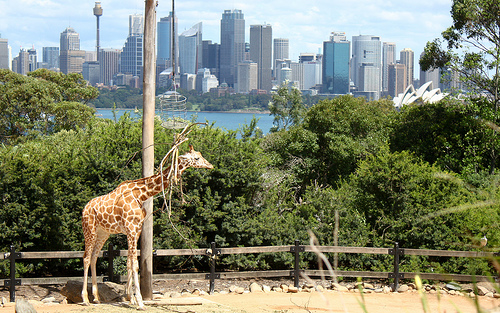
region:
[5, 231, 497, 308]
A wood fence.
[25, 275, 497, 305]
Rocks are lining the fence.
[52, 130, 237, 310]
A giraffe is standing near the fence.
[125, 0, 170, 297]
A wooden pole.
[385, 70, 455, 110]
The roof of the Sydney Opera House.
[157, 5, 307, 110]
Skyscrapers.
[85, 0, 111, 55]
A large slender tower.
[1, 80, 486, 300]
Trees behind the fence.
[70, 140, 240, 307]
The giraffe is yellow and brown.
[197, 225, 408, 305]
The fence is made from wood and metal.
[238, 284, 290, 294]
rocks on the ground.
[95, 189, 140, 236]
giraffe near the pole.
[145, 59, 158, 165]
pole near the giraffe.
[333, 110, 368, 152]
leaves on the trees.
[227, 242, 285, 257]
wooden plank on fence.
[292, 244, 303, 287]
metal reinforcement on fence.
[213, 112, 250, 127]
water near the buildings.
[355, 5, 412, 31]
clouds in the sky.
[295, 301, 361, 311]
dirt on the ground.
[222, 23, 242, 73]
building near the water.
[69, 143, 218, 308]
the giraffe is standing in an enclosure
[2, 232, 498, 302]
a wooden fence is around the pen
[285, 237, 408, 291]
steel posts on the fence are black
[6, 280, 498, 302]
rocks are below the fence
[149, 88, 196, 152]
the giraffe's feeding basket is elevated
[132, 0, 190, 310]
the feeding basket is on a pole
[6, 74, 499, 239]
trees are on the hillside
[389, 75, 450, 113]
the opera house is in the background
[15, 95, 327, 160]
the harbor is behind the giraffe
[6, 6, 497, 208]
the city is behind the zoo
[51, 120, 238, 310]
giraffe standing by a fence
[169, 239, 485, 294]
wooden fence near giraffe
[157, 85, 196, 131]
metal container for food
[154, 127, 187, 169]
hay for giraffe's to eat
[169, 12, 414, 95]
city skyline in the background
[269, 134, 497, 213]
green bushes behind fence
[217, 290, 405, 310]
sandy ground where giraffe stands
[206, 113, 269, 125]
water in front of city skyling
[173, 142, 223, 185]
face of a giraffe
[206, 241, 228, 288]
metal post on a fence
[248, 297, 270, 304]
dirt on the ground.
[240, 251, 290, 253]
fence made of wood.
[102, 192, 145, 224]
giraffe near the post.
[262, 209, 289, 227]
leaves on the tree.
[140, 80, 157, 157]
post near the giraffe.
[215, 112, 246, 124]
water near the city.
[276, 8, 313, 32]
clouds in the sky.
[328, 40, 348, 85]
building near the water.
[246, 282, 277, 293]
rocks on the ground.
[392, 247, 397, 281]
support brace for fence.